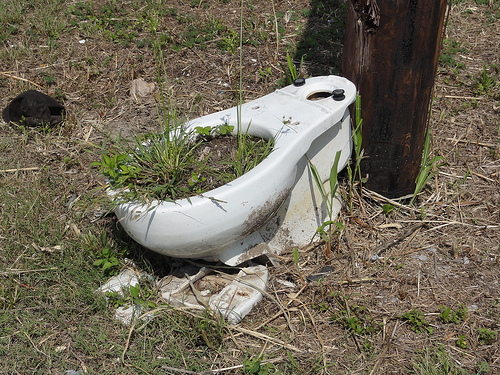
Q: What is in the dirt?
A: Toilet bowl.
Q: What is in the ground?
A: A wooden pole.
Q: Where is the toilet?
A: On ground with grass.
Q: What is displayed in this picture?
A: Dried brown grass and dirt.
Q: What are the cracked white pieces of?
A: Of the toilet.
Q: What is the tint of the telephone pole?
A: Dark brown.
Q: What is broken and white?
A: A toilet bowl.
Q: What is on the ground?
A: A broken toilet.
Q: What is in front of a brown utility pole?
A: A white toilet.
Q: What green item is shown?
A: Grass.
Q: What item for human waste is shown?
A: A toilet.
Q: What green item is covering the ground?
A: Grass.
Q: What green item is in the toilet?
A: Grass.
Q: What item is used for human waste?
A: Toilet.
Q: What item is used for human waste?
A: A toilet.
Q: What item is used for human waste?
A: A toilet.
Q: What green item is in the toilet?
A: Grass.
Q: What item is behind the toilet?
A: A pole.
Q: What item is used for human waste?
A: A toilet.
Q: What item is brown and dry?
A: Grass.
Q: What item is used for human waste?
A: A toilet.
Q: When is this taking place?
A: Daytime.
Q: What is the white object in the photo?
A: Toilet.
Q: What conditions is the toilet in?
A: Broken.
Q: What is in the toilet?
A: Dirt and grass.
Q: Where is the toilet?
A: On the ground.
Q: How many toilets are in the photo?
A: One.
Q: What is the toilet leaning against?
A: Wooden pole.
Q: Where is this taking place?
A: Dirt lot.